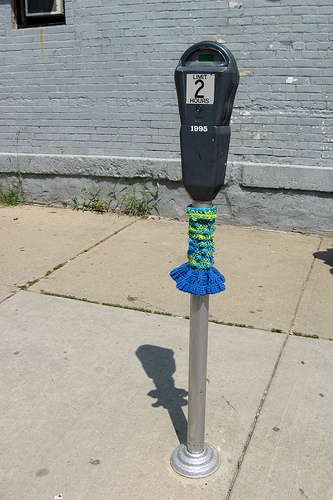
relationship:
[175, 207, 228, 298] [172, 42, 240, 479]
scarf on meter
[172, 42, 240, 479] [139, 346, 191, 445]
meter casting shadow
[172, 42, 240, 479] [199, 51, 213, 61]
meter has a screen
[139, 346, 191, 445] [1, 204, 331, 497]
shadow on pavement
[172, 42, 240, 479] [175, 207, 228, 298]
meter has a scarf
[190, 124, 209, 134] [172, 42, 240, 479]
number on meter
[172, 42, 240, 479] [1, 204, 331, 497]
meter on pavement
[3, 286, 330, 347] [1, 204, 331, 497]
line on pavement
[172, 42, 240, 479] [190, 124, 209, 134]
meter has number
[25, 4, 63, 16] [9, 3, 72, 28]
air conditioner in window